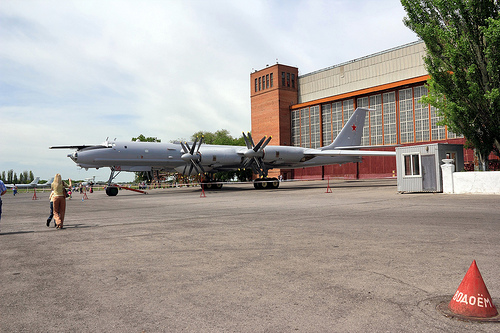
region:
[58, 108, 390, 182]
Airplane near building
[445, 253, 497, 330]
Orange cone in corner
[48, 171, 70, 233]
Woman walking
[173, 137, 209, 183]
Black double propellers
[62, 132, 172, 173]
Front of plane is small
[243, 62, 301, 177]
Red brick tower of building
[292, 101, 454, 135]
Windows of building are tall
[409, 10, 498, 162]
Green tree beside building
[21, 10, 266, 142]
Sky is blue and cloudy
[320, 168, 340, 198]
Red triangle near plane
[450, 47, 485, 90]
the leaves of a tree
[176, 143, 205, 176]
the propeller of a plane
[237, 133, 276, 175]
the propeller of a plane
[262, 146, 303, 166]
the propeller of a plane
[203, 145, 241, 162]
the propeller of a plane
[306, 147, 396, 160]
the wing of a plane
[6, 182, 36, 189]
the wing of a plane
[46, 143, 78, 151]
the wing of a plane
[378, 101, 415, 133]
the windows of a building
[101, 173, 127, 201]
the landing gear of a plane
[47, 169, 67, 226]
woman with long blond hair walking toward airplane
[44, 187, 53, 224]
person dressed in jeans and light colored shirt crossing the path of the woman with long blond hair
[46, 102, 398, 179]
huge grey airplane sitting in a parking lot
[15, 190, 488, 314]
parking lot the lady is walking on and the airplane is sitting on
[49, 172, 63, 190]
womans long blond hair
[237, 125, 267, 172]
front far left propellers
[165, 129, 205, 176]
front propellers left, closer to the airplane body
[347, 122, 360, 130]
red star on the tail runner of the plane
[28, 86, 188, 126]
partly cloudy sky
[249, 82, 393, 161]
brick building with lots of windows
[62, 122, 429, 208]
Airplane parked on concrete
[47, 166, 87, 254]
Woman taking photo of plane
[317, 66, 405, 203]
Tail of large plane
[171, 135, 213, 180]
Propeller on the plane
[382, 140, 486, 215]
Small building on roof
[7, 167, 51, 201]
Planes in the background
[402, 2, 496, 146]
Tree growing by building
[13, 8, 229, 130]
Sky is full of clouds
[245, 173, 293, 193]
Wheels attached to plane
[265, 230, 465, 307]
Cracks in the pavement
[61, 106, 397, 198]
Silver airplane is long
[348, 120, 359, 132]
Red star on tail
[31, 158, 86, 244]
Woman walking near plane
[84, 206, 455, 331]
Concrete is light and gray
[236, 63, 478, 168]
Red building in background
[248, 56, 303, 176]
Red tower of building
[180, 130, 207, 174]
Propeller of airplane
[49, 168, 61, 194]
Woman's hair is blonde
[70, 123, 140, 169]
Nose of plane is relatively small